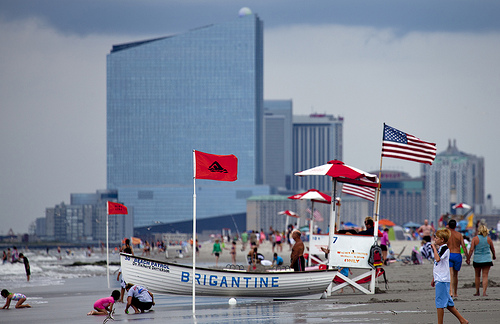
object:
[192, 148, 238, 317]
flag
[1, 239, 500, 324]
sand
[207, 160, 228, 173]
logo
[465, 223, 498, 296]
woman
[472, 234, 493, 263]
tank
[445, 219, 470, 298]
man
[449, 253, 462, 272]
shorts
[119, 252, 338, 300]
boat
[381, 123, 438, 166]
flag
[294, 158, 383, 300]
umbrella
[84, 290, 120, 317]
girl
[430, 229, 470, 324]
boy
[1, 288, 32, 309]
girl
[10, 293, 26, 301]
bathing suit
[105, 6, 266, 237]
building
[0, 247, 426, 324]
water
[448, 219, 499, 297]
couple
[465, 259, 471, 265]
hands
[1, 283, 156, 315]
children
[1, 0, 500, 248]
city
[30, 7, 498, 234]
buildings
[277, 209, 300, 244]
umbrella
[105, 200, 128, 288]
flag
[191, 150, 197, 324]
pole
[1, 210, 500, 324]
people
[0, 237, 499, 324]
beach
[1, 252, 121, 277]
waves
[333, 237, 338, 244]
number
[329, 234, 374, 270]
sign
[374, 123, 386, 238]
pole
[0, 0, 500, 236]
sky